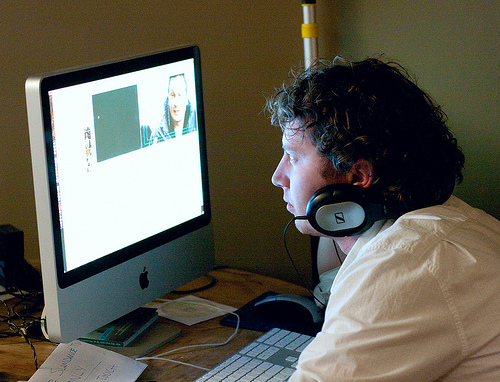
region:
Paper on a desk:
[26, 339, 122, 379]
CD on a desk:
[156, 289, 236, 337]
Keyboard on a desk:
[201, 323, 330, 378]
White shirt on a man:
[313, 216, 498, 380]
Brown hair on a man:
[242, 56, 455, 233]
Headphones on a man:
[291, 158, 372, 247]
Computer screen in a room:
[22, 41, 254, 309]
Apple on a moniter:
[125, 261, 172, 301]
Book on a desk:
[74, 313, 182, 348]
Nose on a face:
[263, 148, 299, 200]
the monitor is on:
[37, 61, 297, 306]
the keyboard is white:
[229, 334, 273, 379]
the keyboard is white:
[216, 320, 260, 367]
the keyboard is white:
[240, 334, 265, 366]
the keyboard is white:
[225, 342, 256, 376]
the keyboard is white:
[223, 304, 251, 362]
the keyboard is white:
[236, 297, 271, 357]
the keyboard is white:
[247, 342, 267, 377]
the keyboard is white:
[250, 330, 277, 377]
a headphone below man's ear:
[291, 171, 383, 246]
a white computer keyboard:
[184, 327, 317, 379]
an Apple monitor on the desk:
[24, 40, 223, 344]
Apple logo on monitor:
[131, 258, 161, 293]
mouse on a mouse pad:
[234, 289, 329, 329]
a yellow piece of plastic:
[295, 13, 325, 48]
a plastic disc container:
[146, 280, 238, 336]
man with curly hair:
[248, 58, 476, 240]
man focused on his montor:
[245, 46, 465, 272]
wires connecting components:
[3, 301, 53, 360]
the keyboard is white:
[172, 262, 339, 379]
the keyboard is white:
[191, 221, 303, 369]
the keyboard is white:
[163, 153, 293, 357]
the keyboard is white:
[165, 226, 253, 352]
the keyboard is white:
[208, 274, 284, 376]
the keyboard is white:
[243, 278, 285, 366]